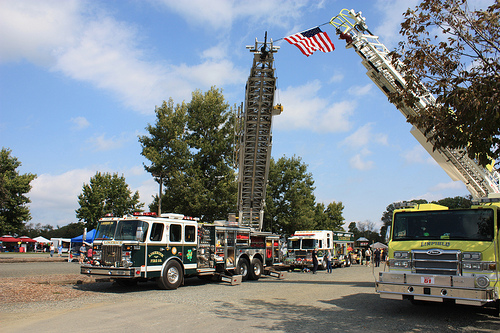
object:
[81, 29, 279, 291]
fire truck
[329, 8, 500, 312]
fire truck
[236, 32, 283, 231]
ladder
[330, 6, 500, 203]
ladder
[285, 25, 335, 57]
flag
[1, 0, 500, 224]
sky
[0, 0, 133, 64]
clouds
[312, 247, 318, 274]
person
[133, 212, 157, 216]
lights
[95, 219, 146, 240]
windshield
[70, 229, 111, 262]
tent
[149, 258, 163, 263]
words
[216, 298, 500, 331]
shadows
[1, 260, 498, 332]
road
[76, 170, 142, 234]
trees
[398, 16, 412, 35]
leaves